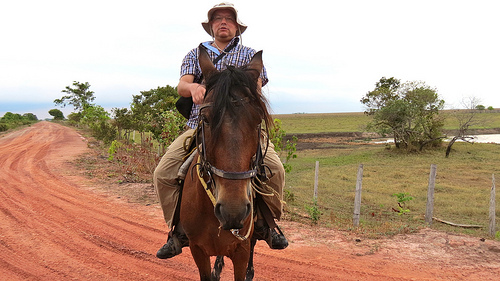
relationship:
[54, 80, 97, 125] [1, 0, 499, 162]
tree in background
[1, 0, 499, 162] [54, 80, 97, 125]
background has a tree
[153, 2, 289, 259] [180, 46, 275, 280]
man riding horse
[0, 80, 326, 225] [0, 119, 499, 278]
trees on path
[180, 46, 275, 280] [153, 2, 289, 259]
horse under man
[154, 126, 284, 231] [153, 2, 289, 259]
pants on man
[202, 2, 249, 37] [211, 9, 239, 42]
hat on mans head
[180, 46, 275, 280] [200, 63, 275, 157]
horse has hair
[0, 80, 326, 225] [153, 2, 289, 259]
trees behind man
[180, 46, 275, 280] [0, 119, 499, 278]
horse on path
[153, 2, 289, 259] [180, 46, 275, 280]
man on horse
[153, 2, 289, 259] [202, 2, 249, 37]
man wearing a hat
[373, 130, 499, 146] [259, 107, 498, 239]
water in field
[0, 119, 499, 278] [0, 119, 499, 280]
path filled with dirt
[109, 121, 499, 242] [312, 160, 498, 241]
fence made of wood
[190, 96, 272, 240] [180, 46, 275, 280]
reins on horse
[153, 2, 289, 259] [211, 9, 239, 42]
man has a head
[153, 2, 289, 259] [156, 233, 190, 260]
man has a foot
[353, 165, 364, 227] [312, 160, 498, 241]
post made of wood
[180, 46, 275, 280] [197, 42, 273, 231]
horse has a head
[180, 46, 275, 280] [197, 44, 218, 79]
horse has an ear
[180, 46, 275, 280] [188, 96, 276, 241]
horse has a reins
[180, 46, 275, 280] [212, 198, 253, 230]
horse has a nose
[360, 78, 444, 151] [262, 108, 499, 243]
tree on grass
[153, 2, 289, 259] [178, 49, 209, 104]
man has an arm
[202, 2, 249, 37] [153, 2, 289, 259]
hat on man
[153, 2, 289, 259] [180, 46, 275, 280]
man riding on horse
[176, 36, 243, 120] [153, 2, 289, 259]
sack on man